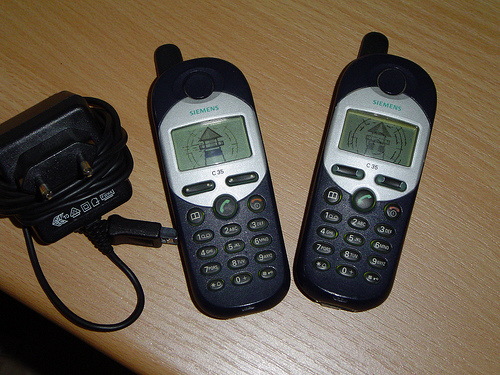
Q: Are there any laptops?
A: No, there are no laptops.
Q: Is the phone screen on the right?
A: Yes, the screen is on the right of the image.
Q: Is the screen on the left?
A: No, the screen is on the right of the image.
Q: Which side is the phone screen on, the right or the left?
A: The screen is on the right of the image.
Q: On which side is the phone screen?
A: The screen is on the right of the image.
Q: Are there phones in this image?
A: Yes, there is a phone.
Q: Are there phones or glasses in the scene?
A: Yes, there is a phone.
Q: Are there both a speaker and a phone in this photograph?
A: Yes, there are both a phone and a speaker.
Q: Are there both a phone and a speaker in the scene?
A: Yes, there are both a phone and a speaker.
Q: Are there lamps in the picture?
A: No, there are no lamps.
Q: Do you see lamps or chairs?
A: No, there are no lamps or chairs.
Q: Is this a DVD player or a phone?
A: This is a phone.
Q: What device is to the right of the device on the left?
A: The device is a phone.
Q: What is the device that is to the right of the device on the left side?
A: The device is a phone.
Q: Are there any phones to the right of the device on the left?
A: Yes, there is a phone to the right of the charger.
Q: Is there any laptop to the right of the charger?
A: No, there is a phone to the right of the charger.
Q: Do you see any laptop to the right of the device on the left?
A: No, there is a phone to the right of the charger.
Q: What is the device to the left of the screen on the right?
A: The device is a phone.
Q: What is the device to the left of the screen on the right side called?
A: The device is a phone.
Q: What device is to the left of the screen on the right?
A: The device is a phone.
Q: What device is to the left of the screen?
A: The device is a phone.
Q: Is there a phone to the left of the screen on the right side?
A: Yes, there is a phone to the left of the screen.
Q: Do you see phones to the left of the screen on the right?
A: Yes, there is a phone to the left of the screen.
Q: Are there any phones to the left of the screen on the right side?
A: Yes, there is a phone to the left of the screen.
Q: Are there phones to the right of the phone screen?
A: No, the phone is to the left of the screen.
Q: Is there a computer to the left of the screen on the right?
A: No, there is a phone to the left of the screen.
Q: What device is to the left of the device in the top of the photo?
A: The device is a phone.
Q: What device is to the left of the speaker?
A: The device is a phone.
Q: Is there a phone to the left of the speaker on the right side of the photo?
A: Yes, there is a phone to the left of the speaker.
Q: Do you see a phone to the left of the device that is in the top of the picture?
A: Yes, there is a phone to the left of the speaker.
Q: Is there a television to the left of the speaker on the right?
A: No, there is a phone to the left of the speaker.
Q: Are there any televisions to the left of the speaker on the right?
A: No, there is a phone to the left of the speaker.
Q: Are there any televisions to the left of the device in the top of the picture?
A: No, there is a phone to the left of the speaker.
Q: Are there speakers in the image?
A: Yes, there is a speaker.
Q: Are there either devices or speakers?
A: Yes, there is a speaker.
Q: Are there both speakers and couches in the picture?
A: No, there is a speaker but no couches.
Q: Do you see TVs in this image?
A: No, there are no tvs.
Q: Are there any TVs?
A: No, there are no tvs.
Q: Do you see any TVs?
A: No, there are no tvs.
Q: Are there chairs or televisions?
A: No, there are no televisions or chairs.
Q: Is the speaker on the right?
A: Yes, the speaker is on the right of the image.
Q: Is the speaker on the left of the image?
A: No, the speaker is on the right of the image.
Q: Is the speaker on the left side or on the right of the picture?
A: The speaker is on the right of the image.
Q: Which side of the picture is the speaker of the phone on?
A: The speaker is on the right of the image.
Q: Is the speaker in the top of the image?
A: Yes, the speaker is in the top of the image.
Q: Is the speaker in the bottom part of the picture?
A: No, the speaker is in the top of the image.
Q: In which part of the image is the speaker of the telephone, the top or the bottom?
A: The speaker is in the top of the image.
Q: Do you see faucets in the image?
A: No, there are no faucets.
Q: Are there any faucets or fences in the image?
A: No, there are no faucets or fences.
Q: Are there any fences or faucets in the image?
A: No, there are no faucets or fences.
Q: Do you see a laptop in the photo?
A: No, there are no laptops.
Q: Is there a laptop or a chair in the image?
A: No, there are no laptops or chairs.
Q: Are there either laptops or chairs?
A: No, there are no laptops or chairs.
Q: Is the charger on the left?
A: Yes, the charger is on the left of the image.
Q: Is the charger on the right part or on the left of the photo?
A: The charger is on the left of the image.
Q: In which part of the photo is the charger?
A: The charger is on the left of the image.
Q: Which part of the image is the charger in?
A: The charger is on the left of the image.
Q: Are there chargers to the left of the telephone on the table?
A: Yes, there is a charger to the left of the telephone.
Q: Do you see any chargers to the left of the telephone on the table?
A: Yes, there is a charger to the left of the telephone.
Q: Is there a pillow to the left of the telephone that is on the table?
A: No, there is a charger to the left of the phone.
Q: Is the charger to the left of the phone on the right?
A: Yes, the charger is to the left of the phone.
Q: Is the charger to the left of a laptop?
A: No, the charger is to the left of the phone.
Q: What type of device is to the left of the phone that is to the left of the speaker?
A: The device is a charger.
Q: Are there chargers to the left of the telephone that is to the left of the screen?
A: Yes, there is a charger to the left of the telephone.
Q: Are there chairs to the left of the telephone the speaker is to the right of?
A: No, there is a charger to the left of the phone.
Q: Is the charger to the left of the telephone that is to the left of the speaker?
A: Yes, the charger is to the left of the telephone.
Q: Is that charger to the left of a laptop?
A: No, the charger is to the left of the telephone.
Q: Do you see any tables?
A: Yes, there is a table.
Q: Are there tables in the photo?
A: Yes, there is a table.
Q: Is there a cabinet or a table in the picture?
A: Yes, there is a table.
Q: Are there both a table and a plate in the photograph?
A: No, there is a table but no plates.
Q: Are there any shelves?
A: No, there are no shelves.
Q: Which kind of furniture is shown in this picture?
A: The furniture is a table.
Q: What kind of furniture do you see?
A: The furniture is a table.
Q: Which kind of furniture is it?
A: The piece of furniture is a table.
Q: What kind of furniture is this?
A: This is a table.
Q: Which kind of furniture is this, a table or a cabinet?
A: This is a table.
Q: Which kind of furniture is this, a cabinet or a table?
A: This is a table.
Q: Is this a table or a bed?
A: This is a table.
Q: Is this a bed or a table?
A: This is a table.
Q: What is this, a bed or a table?
A: This is a table.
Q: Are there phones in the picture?
A: Yes, there is a phone.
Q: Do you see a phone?
A: Yes, there is a phone.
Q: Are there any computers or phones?
A: Yes, there is a phone.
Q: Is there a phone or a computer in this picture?
A: Yes, there is a phone.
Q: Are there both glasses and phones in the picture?
A: No, there is a phone but no glasses.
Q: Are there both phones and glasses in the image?
A: No, there is a phone but no glasses.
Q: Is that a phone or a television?
A: That is a phone.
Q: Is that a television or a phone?
A: That is a phone.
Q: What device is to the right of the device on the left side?
A: The device is a phone.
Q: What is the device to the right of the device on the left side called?
A: The device is a phone.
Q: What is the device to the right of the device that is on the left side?
A: The device is a phone.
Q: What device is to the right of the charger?
A: The device is a phone.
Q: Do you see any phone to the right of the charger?
A: Yes, there is a phone to the right of the charger.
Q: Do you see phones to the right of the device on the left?
A: Yes, there is a phone to the right of the charger.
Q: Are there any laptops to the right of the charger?
A: No, there is a phone to the right of the charger.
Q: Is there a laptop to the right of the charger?
A: No, there is a phone to the right of the charger.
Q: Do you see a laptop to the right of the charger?
A: No, there is a phone to the right of the charger.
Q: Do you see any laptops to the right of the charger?
A: No, there is a phone to the right of the charger.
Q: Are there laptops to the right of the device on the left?
A: No, there is a phone to the right of the charger.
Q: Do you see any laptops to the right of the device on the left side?
A: No, there is a phone to the right of the charger.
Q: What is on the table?
A: The telephone is on the table.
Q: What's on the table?
A: The telephone is on the table.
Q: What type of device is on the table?
A: The device is a phone.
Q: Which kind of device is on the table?
A: The device is a phone.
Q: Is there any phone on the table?
A: Yes, there is a phone on the table.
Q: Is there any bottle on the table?
A: No, there is a phone on the table.